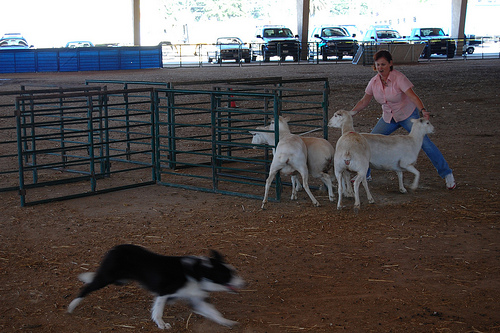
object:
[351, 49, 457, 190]
woman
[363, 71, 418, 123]
shirt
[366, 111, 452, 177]
jeans